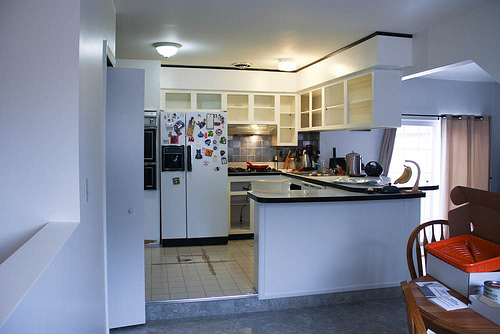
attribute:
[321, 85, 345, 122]
cabinet — white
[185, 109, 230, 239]
refrigerator — white, two door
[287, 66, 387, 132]
cabinet — white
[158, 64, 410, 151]
cabinet — white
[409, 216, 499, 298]
box — white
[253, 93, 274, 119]
door — glass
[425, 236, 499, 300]
box — open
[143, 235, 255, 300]
tile — white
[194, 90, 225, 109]
cabinet — white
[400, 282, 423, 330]
chair — pushed into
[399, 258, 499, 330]
table — wooden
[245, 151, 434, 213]
counter — gray, kitchen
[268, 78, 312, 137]
door — glass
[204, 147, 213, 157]
magnet — several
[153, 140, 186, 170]
dispenser — black, plastic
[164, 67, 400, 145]
cabinets — Kitchen    ,  no doors 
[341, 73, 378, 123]
door — glass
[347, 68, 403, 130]
cabinet — white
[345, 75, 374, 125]
door — glass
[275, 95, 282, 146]
door — glass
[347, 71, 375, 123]
door — glass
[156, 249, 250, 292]
tile — light tan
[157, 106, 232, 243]
refrigerator — Two door 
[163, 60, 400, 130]
cupboards — white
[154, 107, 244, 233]
fridge — white, covered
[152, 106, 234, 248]
fridge — white 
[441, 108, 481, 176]
curtain — beige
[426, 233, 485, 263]
pan — red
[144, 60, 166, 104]
door — glass 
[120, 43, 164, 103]
cabinet — white 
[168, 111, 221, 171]
glare — light  